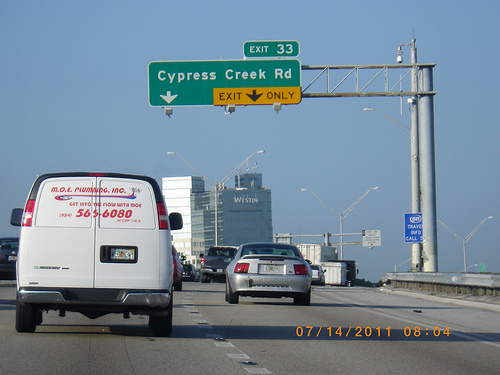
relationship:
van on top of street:
[11, 168, 187, 334] [1, 332, 205, 374]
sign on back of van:
[46, 183, 147, 229] [11, 168, 187, 334]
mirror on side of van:
[167, 210, 184, 232] [11, 168, 187, 334]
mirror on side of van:
[9, 205, 25, 230] [11, 168, 187, 334]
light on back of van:
[156, 202, 169, 234] [11, 168, 187, 334]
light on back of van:
[21, 198, 39, 230] [11, 168, 187, 334]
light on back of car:
[232, 261, 252, 275] [222, 238, 314, 309]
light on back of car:
[293, 260, 312, 278] [222, 238, 314, 309]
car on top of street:
[222, 238, 314, 309] [1, 332, 205, 374]